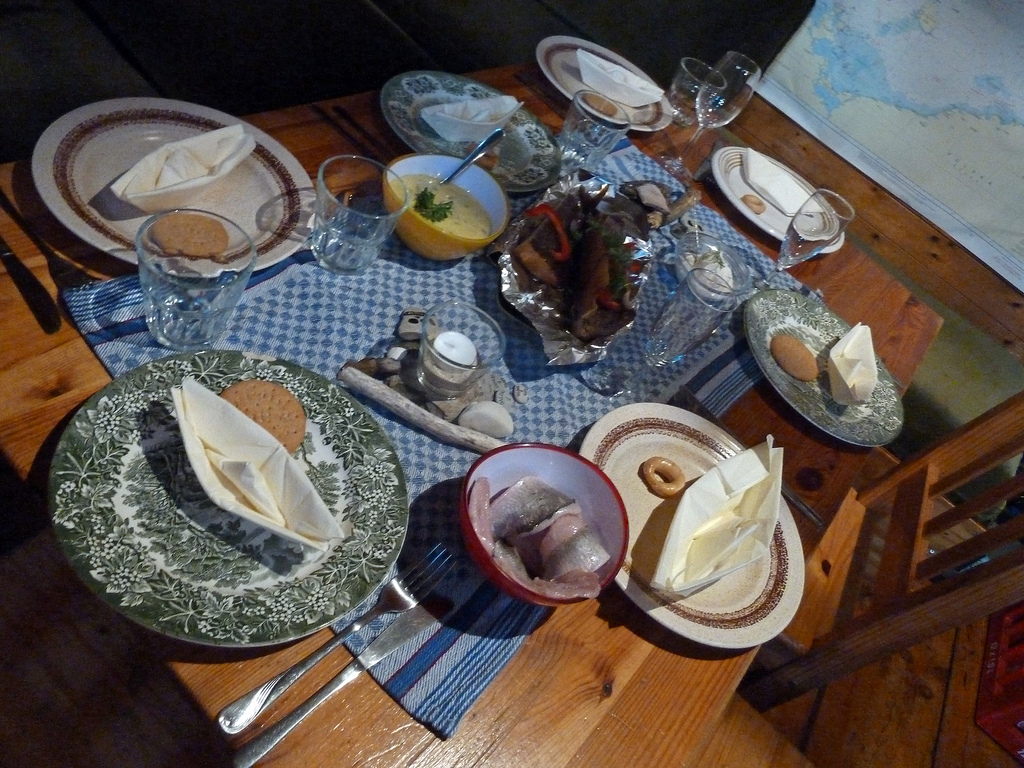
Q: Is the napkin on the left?
A: Yes, the napkin is on the left of the image.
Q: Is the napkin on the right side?
A: No, the napkin is on the left of the image.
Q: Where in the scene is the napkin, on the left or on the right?
A: The napkin is on the left of the image.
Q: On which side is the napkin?
A: The napkin is on the left of the image.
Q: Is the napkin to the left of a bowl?
A: Yes, the napkin is to the left of a bowl.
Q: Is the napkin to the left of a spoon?
A: No, the napkin is to the left of a bowl.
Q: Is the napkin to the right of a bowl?
A: No, the napkin is to the left of a bowl.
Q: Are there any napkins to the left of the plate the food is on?
A: Yes, there is a napkin to the left of the plate.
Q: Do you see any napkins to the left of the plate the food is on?
A: Yes, there is a napkin to the left of the plate.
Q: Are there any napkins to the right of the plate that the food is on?
A: No, the napkin is to the left of the plate.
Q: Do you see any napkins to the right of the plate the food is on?
A: No, the napkin is to the left of the plate.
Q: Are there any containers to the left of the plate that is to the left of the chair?
A: No, there is a napkin to the left of the plate.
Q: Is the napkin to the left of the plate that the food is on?
A: Yes, the napkin is to the left of the plate.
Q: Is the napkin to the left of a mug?
A: No, the napkin is to the left of the plate.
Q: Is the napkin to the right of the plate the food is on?
A: No, the napkin is to the left of the plate.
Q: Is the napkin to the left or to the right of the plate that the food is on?
A: The napkin is to the left of the plate.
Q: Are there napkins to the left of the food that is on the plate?
A: Yes, there is a napkin to the left of the food.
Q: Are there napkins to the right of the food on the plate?
A: No, the napkin is to the left of the food.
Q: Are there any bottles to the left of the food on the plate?
A: No, there is a napkin to the left of the food.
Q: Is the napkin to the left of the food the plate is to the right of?
A: Yes, the napkin is to the left of the food.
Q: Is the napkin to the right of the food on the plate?
A: No, the napkin is to the left of the food.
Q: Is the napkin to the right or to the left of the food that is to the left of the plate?
A: The napkin is to the left of the food.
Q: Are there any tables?
A: Yes, there is a table.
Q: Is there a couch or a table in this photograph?
A: Yes, there is a table.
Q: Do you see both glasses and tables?
A: Yes, there are both a table and glasses.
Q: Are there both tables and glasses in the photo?
A: Yes, there are both a table and glasses.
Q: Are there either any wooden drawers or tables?
A: Yes, there is a wood table.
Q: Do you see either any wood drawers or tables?
A: Yes, there is a wood table.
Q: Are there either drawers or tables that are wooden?
A: Yes, the table is wooden.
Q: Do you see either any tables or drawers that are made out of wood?
A: Yes, the table is made of wood.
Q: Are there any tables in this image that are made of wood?
A: Yes, there is a table that is made of wood.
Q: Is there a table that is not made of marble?
A: Yes, there is a table that is made of wood.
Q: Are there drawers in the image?
A: No, there are no drawers.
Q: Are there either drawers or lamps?
A: No, there are no drawers or lamps.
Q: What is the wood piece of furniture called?
A: The piece of furniture is a table.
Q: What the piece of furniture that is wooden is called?
A: The piece of furniture is a table.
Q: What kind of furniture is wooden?
A: The furniture is a table.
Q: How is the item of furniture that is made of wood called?
A: The piece of furniture is a table.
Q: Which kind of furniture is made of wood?
A: The furniture is a table.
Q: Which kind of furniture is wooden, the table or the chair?
A: The table is wooden.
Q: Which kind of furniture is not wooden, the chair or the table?
A: The chair is not wooden.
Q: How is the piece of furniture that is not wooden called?
A: The piece of furniture is a chair.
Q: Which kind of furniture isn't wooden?
A: The furniture is a chair.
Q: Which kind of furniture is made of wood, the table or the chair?
A: The table is made of wood.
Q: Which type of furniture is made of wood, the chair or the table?
A: The table is made of wood.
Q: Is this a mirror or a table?
A: This is a table.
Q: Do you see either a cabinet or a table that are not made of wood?
A: No, there is a table but it is made of wood.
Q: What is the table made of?
A: The table is made of wood.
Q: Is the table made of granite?
A: No, the table is made of wood.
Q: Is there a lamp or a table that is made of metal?
A: No, there is a table but it is made of wood.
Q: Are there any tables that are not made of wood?
A: No, there is a table but it is made of wood.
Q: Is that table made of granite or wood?
A: The table is made of wood.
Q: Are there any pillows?
A: No, there are no pillows.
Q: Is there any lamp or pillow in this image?
A: No, there are no pillows or lamps.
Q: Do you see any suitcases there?
A: No, there are no suitcases.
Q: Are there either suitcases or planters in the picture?
A: No, there are no suitcases or planters.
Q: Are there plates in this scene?
A: Yes, there is a plate.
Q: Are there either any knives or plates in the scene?
A: Yes, there is a plate.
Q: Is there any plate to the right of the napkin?
A: Yes, there is a plate to the right of the napkin.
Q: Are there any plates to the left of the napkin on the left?
A: No, the plate is to the right of the napkin.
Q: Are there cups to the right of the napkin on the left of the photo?
A: No, there is a plate to the right of the napkin.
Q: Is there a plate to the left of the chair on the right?
A: Yes, there is a plate to the left of the chair.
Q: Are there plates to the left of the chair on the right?
A: Yes, there is a plate to the left of the chair.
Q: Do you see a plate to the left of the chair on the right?
A: Yes, there is a plate to the left of the chair.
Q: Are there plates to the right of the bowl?
A: Yes, there is a plate to the right of the bowl.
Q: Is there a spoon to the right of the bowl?
A: No, there is a plate to the right of the bowl.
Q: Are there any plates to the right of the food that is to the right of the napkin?
A: Yes, there is a plate to the right of the food.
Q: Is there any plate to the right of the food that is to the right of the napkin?
A: Yes, there is a plate to the right of the food.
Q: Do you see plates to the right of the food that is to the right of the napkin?
A: Yes, there is a plate to the right of the food.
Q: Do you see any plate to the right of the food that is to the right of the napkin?
A: Yes, there is a plate to the right of the food.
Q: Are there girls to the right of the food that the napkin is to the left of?
A: No, there is a plate to the right of the food.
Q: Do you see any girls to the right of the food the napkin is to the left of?
A: No, there is a plate to the right of the food.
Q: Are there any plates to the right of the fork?
A: Yes, there is a plate to the right of the fork.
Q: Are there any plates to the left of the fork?
A: No, the plate is to the right of the fork.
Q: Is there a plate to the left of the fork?
A: No, the plate is to the right of the fork.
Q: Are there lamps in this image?
A: No, there are no lamps.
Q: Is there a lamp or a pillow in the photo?
A: No, there are no lamps or pillows.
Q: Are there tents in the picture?
A: No, there are no tents.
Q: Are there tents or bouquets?
A: No, there are no tents or bouquets.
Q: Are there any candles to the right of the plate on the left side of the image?
A: Yes, there is a candle to the right of the plate.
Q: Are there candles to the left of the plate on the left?
A: No, the candle is to the right of the plate.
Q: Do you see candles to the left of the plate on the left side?
A: No, the candle is to the right of the plate.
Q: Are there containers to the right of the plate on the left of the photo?
A: No, there is a candle to the right of the plate.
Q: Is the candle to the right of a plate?
A: Yes, the candle is to the right of a plate.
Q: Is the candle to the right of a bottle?
A: No, the candle is to the right of a plate.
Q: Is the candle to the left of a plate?
A: No, the candle is to the right of a plate.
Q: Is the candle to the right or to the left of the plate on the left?
A: The candle is to the right of the plate.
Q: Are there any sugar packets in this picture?
A: No, there are no sugar packets.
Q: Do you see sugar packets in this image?
A: No, there are no sugar packets.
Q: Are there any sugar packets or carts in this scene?
A: No, there are no sugar packets or carts.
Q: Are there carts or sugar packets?
A: No, there are no sugar packets or carts.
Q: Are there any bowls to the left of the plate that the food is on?
A: Yes, there is a bowl to the left of the plate.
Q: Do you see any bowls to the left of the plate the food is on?
A: Yes, there is a bowl to the left of the plate.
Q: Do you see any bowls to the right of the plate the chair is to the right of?
A: No, the bowl is to the left of the plate.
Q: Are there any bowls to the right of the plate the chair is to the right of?
A: No, the bowl is to the left of the plate.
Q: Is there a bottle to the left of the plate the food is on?
A: No, there is a bowl to the left of the plate.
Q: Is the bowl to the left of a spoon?
A: No, the bowl is to the left of a plate.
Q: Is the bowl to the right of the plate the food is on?
A: No, the bowl is to the left of the plate.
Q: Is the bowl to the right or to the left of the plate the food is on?
A: The bowl is to the left of the plate.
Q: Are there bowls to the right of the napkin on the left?
A: Yes, there is a bowl to the right of the napkin.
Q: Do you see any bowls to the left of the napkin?
A: No, the bowl is to the right of the napkin.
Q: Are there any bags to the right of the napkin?
A: No, there is a bowl to the right of the napkin.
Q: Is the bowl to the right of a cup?
A: No, the bowl is to the right of a napkin.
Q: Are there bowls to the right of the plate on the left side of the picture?
A: Yes, there is a bowl to the right of the plate.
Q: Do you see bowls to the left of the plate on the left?
A: No, the bowl is to the right of the plate.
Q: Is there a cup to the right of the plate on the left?
A: No, there is a bowl to the right of the plate.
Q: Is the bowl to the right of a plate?
A: Yes, the bowl is to the right of a plate.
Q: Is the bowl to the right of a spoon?
A: No, the bowl is to the right of a plate.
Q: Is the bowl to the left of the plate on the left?
A: No, the bowl is to the right of the plate.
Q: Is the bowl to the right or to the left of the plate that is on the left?
A: The bowl is to the right of the plate.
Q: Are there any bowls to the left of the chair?
A: Yes, there is a bowl to the left of the chair.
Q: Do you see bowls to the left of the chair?
A: Yes, there is a bowl to the left of the chair.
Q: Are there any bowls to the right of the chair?
A: No, the bowl is to the left of the chair.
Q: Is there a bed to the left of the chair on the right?
A: No, there is a bowl to the left of the chair.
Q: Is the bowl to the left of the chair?
A: Yes, the bowl is to the left of the chair.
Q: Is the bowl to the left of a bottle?
A: No, the bowl is to the left of the chair.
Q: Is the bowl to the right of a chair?
A: No, the bowl is to the left of a chair.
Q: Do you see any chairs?
A: Yes, there is a chair.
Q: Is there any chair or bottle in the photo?
A: Yes, there is a chair.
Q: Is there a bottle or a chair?
A: Yes, there is a chair.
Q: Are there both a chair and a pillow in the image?
A: No, there is a chair but no pillows.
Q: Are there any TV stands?
A: No, there are no TV stands.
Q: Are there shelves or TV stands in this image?
A: No, there are no TV stands or shelves.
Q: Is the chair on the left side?
A: No, the chair is on the right of the image.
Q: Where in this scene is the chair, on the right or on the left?
A: The chair is on the right of the image.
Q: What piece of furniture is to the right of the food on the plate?
A: The piece of furniture is a chair.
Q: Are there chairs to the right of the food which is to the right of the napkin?
A: Yes, there is a chair to the right of the food.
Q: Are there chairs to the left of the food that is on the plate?
A: No, the chair is to the right of the food.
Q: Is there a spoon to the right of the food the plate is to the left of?
A: No, there is a chair to the right of the food.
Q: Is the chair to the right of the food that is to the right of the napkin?
A: Yes, the chair is to the right of the food.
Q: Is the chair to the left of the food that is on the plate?
A: No, the chair is to the right of the food.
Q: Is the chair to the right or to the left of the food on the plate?
A: The chair is to the right of the food.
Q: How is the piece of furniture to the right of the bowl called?
A: The piece of furniture is a chair.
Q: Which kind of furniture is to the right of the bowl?
A: The piece of furniture is a chair.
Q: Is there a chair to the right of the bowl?
A: Yes, there is a chair to the right of the bowl.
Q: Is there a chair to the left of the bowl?
A: No, the chair is to the right of the bowl.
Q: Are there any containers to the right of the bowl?
A: No, there is a chair to the right of the bowl.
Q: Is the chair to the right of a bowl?
A: Yes, the chair is to the right of a bowl.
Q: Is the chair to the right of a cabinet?
A: No, the chair is to the right of a bowl.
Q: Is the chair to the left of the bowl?
A: No, the chair is to the right of the bowl.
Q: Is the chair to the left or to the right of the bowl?
A: The chair is to the right of the bowl.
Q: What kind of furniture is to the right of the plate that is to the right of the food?
A: The piece of furniture is a chair.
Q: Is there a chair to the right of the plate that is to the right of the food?
A: Yes, there is a chair to the right of the plate.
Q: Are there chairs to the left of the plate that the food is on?
A: No, the chair is to the right of the plate.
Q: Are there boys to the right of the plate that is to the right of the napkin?
A: No, there is a chair to the right of the plate.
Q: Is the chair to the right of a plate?
A: Yes, the chair is to the right of a plate.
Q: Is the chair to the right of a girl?
A: No, the chair is to the right of a plate.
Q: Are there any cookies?
A: Yes, there is a cookie.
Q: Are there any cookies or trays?
A: Yes, there is a cookie.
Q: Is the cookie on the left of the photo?
A: Yes, the cookie is on the left of the image.